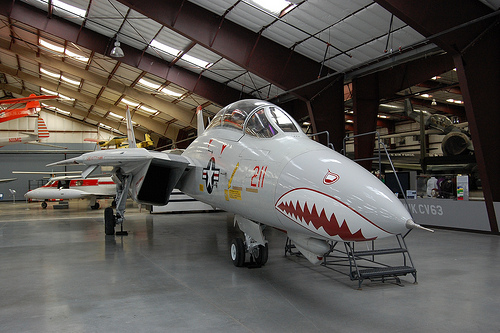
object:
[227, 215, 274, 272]
landing gear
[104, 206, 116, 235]
wheel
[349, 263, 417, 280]
metal steps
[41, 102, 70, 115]
plane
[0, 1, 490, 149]
ceiling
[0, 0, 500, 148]
roof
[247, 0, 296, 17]
panel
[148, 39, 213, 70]
panel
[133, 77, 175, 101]
panel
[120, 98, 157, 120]
panel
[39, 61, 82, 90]
panel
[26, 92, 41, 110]
tail wing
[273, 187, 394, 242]
paint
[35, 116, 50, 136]
tail wing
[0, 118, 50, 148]
plane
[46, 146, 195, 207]
wing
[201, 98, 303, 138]
cockpit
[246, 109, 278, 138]
windshield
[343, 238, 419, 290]
ladder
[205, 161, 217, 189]
star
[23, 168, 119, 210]
plane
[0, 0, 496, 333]
hangar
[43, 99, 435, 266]
fighter jet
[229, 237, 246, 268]
wheels